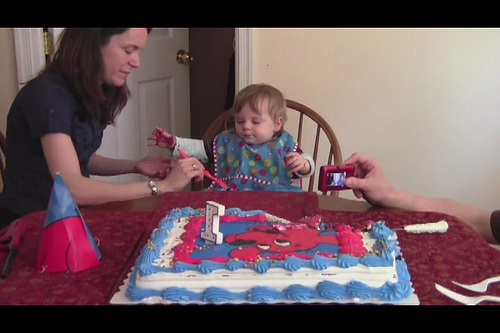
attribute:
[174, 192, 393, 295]
cake — red, blue, white, ready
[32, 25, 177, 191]
woman — feeding, sitting, white, skinny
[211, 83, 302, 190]
child — toddler, sitting, small, white, eating, close, siting, happy